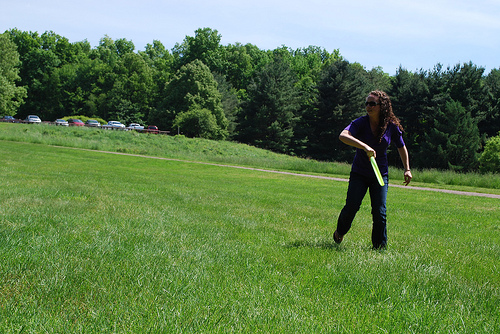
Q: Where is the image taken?
A: Field.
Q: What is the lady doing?
A: Frisbee.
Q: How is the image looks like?
A: Interesting.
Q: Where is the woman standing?
A: On a grassy field.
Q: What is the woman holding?
A: A frisbee.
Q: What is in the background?
A: Many trees.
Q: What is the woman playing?
A: Frisbee.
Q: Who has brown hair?
A: The woman.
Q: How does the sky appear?
A: Blue and clear.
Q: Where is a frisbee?
A: In woman's hand.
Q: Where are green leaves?
A: On the trees.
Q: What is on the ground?
A: Grass.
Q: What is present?
A: A woman.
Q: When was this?
A: Daytime.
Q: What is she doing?
A: Playing.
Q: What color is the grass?
A: Green.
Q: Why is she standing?
A: To play.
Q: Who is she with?
A: Nobody.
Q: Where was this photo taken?
A: On a grassy field.